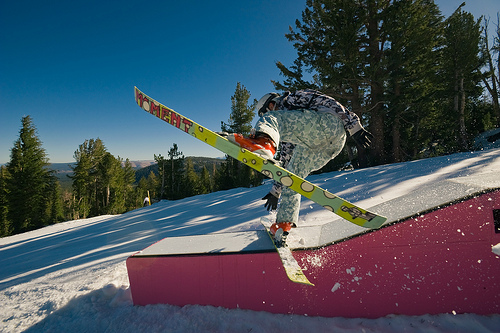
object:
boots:
[221, 127, 286, 159]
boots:
[259, 215, 301, 248]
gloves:
[343, 118, 381, 151]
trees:
[146, 148, 173, 204]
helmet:
[250, 88, 281, 119]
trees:
[204, 66, 280, 187]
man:
[219, 79, 380, 250]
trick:
[125, 77, 492, 316]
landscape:
[0, 0, 500, 333]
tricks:
[217, 69, 385, 248]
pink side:
[121, 191, 500, 313]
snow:
[0, 222, 122, 331]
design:
[338, 202, 378, 222]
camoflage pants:
[251, 107, 351, 228]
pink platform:
[122, 169, 500, 320]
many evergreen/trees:
[165, 137, 185, 197]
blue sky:
[0, 0, 500, 162]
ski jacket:
[270, 87, 364, 191]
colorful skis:
[132, 82, 390, 230]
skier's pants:
[248, 106, 352, 230]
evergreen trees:
[0, 108, 64, 235]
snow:
[14, 219, 109, 261]